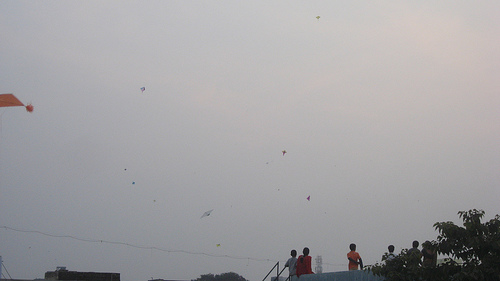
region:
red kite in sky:
[1, 84, 87, 137]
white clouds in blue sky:
[7, 19, 66, 62]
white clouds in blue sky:
[77, 22, 127, 66]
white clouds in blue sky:
[60, 98, 95, 130]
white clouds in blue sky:
[50, 168, 98, 203]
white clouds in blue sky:
[227, 77, 265, 97]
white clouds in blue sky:
[309, 40, 345, 76]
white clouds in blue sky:
[364, 80, 402, 135]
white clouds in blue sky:
[397, 18, 450, 66]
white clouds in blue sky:
[366, 98, 433, 152]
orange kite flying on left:
[0, 86, 33, 115]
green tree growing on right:
[390, 190, 495, 250]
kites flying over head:
[145, 65, 322, 222]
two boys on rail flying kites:
[278, 245, 338, 273]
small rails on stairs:
[247, 256, 274, 279]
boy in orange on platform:
[339, 231, 374, 279]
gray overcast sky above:
[52, 32, 444, 221]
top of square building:
[34, 252, 139, 279]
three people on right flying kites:
[382, 222, 454, 272]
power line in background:
[8, 197, 250, 267]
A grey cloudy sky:
[1, 1, 498, 278]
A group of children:
[283, 231, 442, 274]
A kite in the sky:
[1, 85, 34, 117]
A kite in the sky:
[303, 193, 315, 203]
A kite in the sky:
[260, 146, 290, 168]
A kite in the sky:
[312, 12, 324, 25]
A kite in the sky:
[134, 82, 149, 95]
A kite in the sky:
[120, 163, 130, 172]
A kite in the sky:
[193, 205, 218, 219]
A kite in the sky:
[215, 239, 222, 248]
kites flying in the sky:
[82, 10, 425, 226]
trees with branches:
[393, 212, 499, 274]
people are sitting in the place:
[265, 227, 498, 279]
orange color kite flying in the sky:
[1, 86, 46, 146]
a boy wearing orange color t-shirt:
[342, 252, 371, 274]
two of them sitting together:
[281, 245, 316, 280]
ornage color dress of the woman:
[299, 256, 312, 273]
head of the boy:
[347, 242, 359, 255]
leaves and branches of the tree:
[441, 212, 498, 273]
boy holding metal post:
[261, 256, 296, 279]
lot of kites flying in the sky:
[106, 15, 392, 210]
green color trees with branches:
[438, 217, 498, 277]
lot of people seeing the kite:
[286, 240, 455, 279]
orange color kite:
[0, 84, 47, 122]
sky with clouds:
[93, 43, 439, 209]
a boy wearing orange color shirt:
[343, 245, 365, 270]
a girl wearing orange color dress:
[296, 246, 318, 278]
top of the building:
[38, 263, 130, 278]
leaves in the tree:
[446, 224, 479, 261]